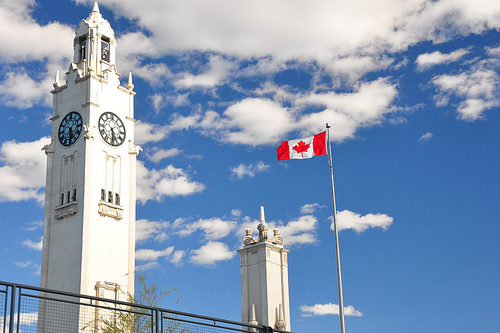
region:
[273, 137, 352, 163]
Canadian flag on a pole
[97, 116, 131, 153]
Clock on a building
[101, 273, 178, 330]
Tree behind a fence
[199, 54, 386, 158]
Sky with clouds in it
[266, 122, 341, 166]
Red and white flag on a pole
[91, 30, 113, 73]
Glass window frame on tower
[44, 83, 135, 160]
Clock on a tower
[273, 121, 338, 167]
Red and white Canadian flag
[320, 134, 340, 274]
Pole with a flag on it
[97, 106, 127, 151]
Clock showing 5:30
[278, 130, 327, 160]
the canadian flag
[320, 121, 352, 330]
a flag pole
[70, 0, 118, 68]
a white spire on a tower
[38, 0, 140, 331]
a white clock tower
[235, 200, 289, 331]
a white tower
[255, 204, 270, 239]
a simple white spire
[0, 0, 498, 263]
wispy white clouds in the sky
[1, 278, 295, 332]
a black metal fence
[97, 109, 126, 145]
a clock on the front of a tower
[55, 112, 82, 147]
a clock on the side of a tower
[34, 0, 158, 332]
a clock tower is behind a fence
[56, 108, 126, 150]
two clocks are displayed on the tower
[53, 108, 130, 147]
the clock's faces are black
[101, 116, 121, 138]
the center of the clock face has a blue design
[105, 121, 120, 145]
the hands of the clock are black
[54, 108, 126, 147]
the clocks roman numerals are black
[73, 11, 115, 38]
the dome of the tower is white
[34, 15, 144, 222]
finials and parapets are all over the tower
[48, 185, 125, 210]
arched windows are on the tower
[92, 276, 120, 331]
the door of the clock tower is closed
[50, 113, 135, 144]
two clocks in the tower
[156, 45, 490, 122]
a beautiful sunny day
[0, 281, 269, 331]
the metal protective fence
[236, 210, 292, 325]
white small tower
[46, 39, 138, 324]
a large white tower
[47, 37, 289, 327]
two white towers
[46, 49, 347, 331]
two towers and canadian flag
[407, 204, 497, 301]
color blue in the sky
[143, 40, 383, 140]
a lot of clouds in the sky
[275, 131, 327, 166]
Canadian flag on pole.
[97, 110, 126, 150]
Clock on the side of the building.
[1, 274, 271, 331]
Black fence in the forefront.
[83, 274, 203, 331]
Tree in the forefront.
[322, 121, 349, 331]
Silver flag pole in forefront.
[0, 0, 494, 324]
White clouds in the sky.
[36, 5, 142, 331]
White tower in the background.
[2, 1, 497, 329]
Blue sky in the background.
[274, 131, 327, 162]
Red and white colors on the flag.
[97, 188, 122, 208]
Windows in the building.